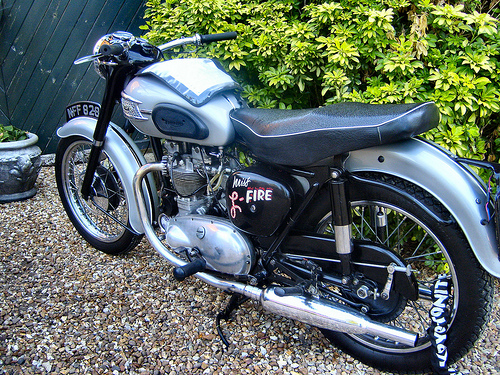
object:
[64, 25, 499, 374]
motorcycle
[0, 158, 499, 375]
driveway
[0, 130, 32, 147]
plant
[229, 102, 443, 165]
seat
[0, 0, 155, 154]
fence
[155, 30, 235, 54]
handlebar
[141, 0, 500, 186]
tree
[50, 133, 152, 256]
wheel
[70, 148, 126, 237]
spokes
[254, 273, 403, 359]
exhaust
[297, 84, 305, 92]
leaves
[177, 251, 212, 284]
pedal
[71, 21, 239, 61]
steering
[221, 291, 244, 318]
stand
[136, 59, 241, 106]
mat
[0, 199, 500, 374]
rocks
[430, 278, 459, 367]
words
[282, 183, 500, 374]
tire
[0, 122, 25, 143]
flower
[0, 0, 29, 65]
siding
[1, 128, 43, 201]
planter